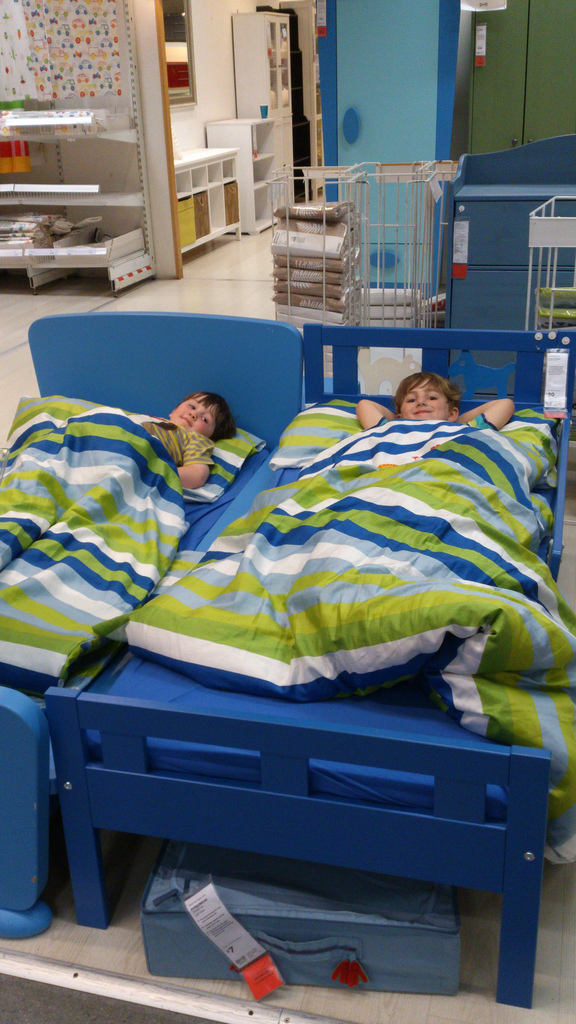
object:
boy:
[351, 369, 519, 449]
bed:
[45, 321, 575, 1014]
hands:
[383, 392, 466, 435]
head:
[392, 367, 460, 424]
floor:
[0, 859, 576, 1019]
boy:
[76, 389, 239, 495]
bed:
[0, 309, 308, 939]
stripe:
[128, 613, 481, 686]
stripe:
[125, 592, 482, 629]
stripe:
[0, 539, 131, 614]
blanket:
[139, 403, 576, 779]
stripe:
[139, 586, 482, 635]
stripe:
[196, 544, 529, 598]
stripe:
[200, 536, 569, 577]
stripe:
[257, 464, 528, 495]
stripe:
[269, 432, 518, 472]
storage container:
[139, 835, 462, 998]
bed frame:
[41, 679, 551, 1019]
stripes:
[301, 414, 540, 456]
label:
[451, 219, 471, 263]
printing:
[454, 223, 467, 260]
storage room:
[152, 2, 335, 275]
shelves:
[222, 176, 242, 231]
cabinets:
[232, 0, 298, 235]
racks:
[318, 177, 331, 319]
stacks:
[276, 301, 347, 324]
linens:
[272, 202, 355, 222]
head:
[169, 387, 236, 443]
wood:
[250, 747, 315, 801]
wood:
[97, 728, 150, 779]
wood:
[44, 685, 109, 928]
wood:
[85, 760, 505, 899]